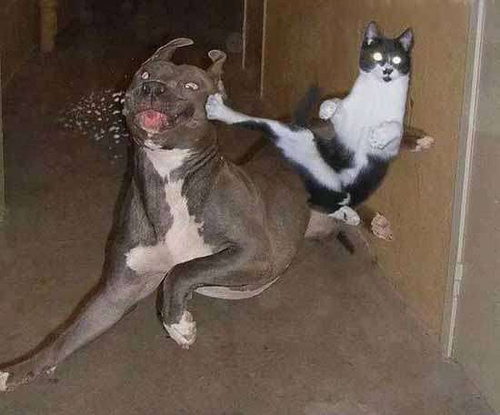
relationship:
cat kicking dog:
[207, 22, 412, 213] [0, 36, 437, 391]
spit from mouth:
[51, 87, 131, 163] [124, 103, 194, 146]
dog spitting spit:
[2, 37, 372, 393] [60, 89, 124, 142]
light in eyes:
[371, 46, 415, 74] [370, 52, 402, 64]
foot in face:
[201, 89, 239, 126] [114, 28, 231, 151]